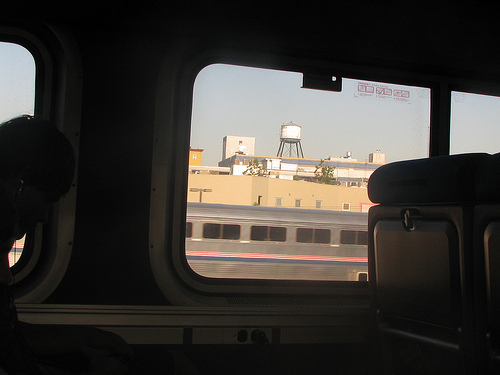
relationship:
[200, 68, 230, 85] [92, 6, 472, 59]
window in train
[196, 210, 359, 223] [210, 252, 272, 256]
train car has stripe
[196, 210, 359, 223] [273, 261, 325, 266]
train car has stripe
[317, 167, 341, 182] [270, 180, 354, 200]
bush between building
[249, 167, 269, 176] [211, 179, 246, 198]
bush between building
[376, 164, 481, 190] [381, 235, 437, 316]
seat has tray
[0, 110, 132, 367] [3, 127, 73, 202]
passenger has head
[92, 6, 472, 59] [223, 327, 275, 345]
train has outlet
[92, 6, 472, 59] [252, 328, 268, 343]
train has outlet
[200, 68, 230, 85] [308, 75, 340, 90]
window has latch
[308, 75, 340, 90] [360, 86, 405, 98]
latch has instructions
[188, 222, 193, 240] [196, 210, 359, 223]
window on train car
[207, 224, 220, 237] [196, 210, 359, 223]
window on train car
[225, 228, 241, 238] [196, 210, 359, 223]
window on train car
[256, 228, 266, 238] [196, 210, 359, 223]
window on train car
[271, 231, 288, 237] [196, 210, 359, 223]
window on train car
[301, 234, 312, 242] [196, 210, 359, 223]
window on train car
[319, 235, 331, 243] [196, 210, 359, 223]
window on train car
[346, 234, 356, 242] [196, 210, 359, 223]
window on train car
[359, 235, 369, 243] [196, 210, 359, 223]
window on train car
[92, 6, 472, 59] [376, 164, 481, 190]
train has seat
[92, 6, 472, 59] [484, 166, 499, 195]
train has seat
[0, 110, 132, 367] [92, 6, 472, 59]
passenger in train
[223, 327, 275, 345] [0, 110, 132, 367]
outlet in front of passenger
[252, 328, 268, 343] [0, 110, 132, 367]
outlet in front of passenger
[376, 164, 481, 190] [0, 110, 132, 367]
seat in front of passenger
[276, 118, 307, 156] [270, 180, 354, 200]
water tower above building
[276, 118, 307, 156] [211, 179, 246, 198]
water tower above building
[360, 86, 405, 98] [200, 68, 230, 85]
instructions on window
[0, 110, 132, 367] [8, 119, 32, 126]
passenger has hair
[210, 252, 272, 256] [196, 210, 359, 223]
stripe on train car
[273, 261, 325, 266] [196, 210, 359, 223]
stripe on train car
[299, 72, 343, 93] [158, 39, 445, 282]
latch on window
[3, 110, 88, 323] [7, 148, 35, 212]
passenger wearing headphones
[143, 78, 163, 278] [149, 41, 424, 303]
screws on window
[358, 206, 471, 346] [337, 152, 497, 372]
tray on seat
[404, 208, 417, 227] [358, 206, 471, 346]
latch on tray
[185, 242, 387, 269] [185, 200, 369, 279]
stripes on train car